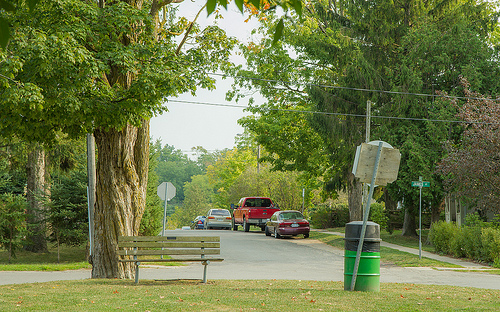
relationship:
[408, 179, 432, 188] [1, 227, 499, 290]
sign beside road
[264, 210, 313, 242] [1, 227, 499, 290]
car beside road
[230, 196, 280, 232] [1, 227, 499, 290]
car beside road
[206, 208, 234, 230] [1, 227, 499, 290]
car beside road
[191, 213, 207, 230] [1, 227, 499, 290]
car beside road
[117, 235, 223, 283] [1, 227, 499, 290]
bench beside of road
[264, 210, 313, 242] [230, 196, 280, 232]
car beside car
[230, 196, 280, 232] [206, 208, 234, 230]
car behind car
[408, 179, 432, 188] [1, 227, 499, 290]
sign beside of road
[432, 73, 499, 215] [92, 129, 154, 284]
tree has a trunk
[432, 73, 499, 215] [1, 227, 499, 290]
tree beside of road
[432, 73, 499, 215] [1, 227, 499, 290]
tree are beside of road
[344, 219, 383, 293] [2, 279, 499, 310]
trash can sitting on grass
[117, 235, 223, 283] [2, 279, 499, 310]
bench sitting on grass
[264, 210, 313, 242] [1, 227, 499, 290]
car parked on road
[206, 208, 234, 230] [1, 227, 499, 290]
car parked on road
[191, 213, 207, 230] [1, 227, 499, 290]
car parked on road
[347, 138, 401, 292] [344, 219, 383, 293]
sign behind trash can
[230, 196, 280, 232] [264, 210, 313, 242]
car next to car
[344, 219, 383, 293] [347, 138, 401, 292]
trash can in front of sign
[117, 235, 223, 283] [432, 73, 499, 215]
bench in front of tree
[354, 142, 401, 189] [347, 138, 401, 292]
wooden block behind sign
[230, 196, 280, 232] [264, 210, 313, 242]
car in front of car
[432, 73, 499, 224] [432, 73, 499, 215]
tree beside of tree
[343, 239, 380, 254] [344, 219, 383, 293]
bag inside of trash can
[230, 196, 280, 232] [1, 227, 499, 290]
car beside of road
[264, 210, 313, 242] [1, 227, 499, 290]
car parked beside road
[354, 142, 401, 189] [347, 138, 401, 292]
wooden block on sign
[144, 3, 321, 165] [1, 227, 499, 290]
sky above road